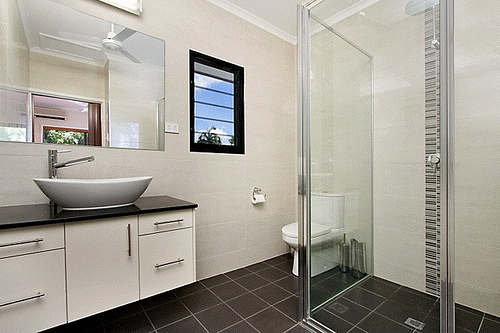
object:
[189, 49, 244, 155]
black trim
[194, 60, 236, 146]
window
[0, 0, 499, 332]
bathroom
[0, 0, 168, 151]
mirror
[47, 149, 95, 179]
faucet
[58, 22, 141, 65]
fan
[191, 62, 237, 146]
frame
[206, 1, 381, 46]
ceiling trim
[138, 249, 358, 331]
tile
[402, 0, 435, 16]
shower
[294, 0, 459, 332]
door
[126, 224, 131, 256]
handle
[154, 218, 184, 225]
handle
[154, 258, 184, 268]
handle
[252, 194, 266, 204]
toilet paper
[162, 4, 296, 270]
wall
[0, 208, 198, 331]
vanity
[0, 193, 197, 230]
top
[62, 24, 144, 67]
ceiling fan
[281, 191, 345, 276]
toilet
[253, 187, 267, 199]
holder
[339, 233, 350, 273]
toiletbrush holder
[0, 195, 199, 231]
counter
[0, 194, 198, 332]
cabinets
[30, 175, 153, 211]
sink